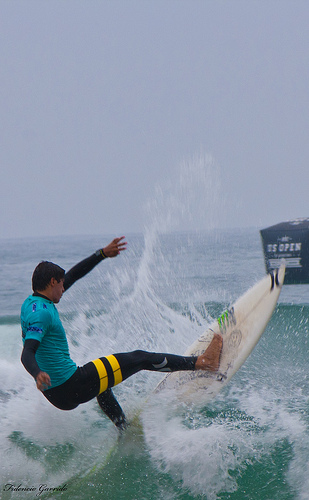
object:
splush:
[71, 221, 194, 337]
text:
[266, 242, 302, 252]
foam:
[4, 144, 308, 497]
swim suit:
[20, 248, 198, 435]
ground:
[188, 94, 200, 112]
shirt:
[20, 292, 79, 391]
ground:
[189, 118, 219, 142]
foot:
[196, 329, 224, 372]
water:
[0, 144, 307, 366]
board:
[128, 262, 286, 429]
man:
[20, 235, 224, 430]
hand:
[104, 235, 128, 257]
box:
[257, 218, 308, 287]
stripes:
[269, 268, 274, 289]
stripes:
[268, 270, 274, 289]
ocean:
[5, 231, 306, 498]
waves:
[94, 283, 204, 355]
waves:
[1, 401, 300, 473]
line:
[88, 353, 123, 398]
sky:
[2, 0, 305, 238]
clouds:
[77, 89, 198, 190]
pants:
[40, 350, 198, 434]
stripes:
[90, 353, 123, 397]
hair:
[32, 260, 66, 293]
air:
[3, 153, 299, 311]